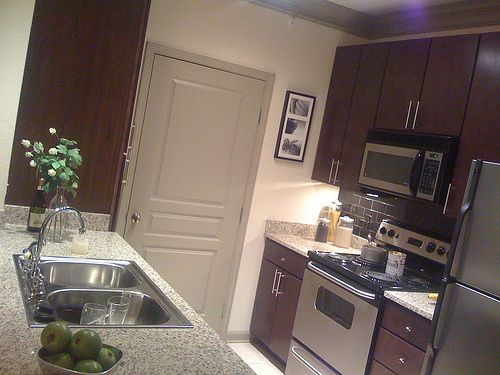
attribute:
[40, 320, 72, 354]
apple — green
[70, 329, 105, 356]
apple — green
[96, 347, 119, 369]
apple — green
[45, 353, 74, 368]
apple — green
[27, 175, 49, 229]
bottle — corked, wine, green, white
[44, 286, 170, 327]
sink — steel, stainless, silver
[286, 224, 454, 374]
stove — electric, steel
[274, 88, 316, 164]
picture — framed, hanging, black, white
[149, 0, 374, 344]
wall — white, painted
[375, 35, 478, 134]
cupboard — brown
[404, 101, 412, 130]
handle — silver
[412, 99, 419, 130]
handle — silver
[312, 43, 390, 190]
cupboard — brown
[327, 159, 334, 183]
handle — silver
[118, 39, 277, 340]
door — gray, present, taupe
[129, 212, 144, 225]
knob — silver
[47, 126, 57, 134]
flower — white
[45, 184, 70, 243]
vase — clear, glass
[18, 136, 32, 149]
flower — white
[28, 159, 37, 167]
flower — white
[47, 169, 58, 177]
rose — white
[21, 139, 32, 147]
rose — white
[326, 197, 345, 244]
jar — glass, large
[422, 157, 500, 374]
fridge — steel, stainless, present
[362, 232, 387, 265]
pot — metal, silver, cooking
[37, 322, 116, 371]
apples — green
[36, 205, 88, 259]
faucet — stainless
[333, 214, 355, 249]
jar — glass, large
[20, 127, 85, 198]
plant — white, green